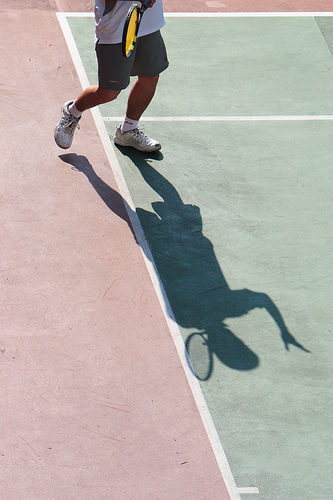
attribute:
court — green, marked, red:
[2, 1, 332, 499]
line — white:
[54, 6, 243, 499]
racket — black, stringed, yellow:
[121, 1, 153, 61]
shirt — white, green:
[92, 0, 168, 47]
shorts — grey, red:
[95, 27, 170, 91]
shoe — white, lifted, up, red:
[113, 122, 162, 155]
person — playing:
[52, 1, 171, 153]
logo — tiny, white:
[108, 76, 121, 82]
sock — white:
[119, 117, 138, 131]